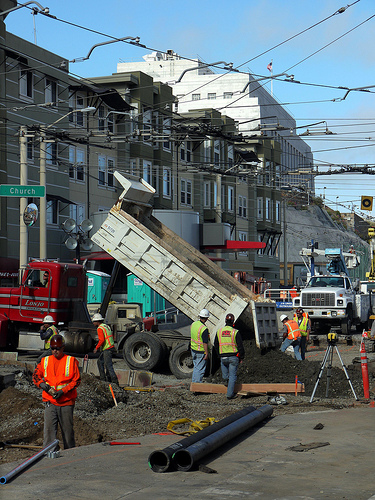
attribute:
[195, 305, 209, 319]
vest — yellow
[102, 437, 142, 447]
pipe wrench — red handled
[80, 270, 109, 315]
port-a-potty — green, white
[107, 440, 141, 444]
tool — red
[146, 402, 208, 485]
sewer pipe — black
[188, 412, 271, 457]
sewer pipe — black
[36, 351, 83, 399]
reflective vest — orange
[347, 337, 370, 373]
safety cone — orange, white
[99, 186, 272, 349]
dump truck — white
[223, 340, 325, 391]
dirt — dark brown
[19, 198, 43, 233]
mirror — round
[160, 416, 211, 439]
strap — yellow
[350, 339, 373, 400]
pole — red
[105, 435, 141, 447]
tool — red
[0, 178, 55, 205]
sign — green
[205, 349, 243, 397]
jeans — blue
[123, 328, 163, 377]
tire — black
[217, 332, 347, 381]
gravel — dark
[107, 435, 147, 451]
handle — red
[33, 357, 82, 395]
vest — orange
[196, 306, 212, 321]
safety helmet — white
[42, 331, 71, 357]
helmet — black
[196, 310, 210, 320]
helmet — white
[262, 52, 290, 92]
flag — American flag